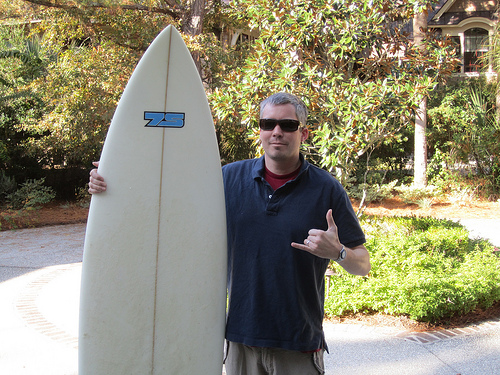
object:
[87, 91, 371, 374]
man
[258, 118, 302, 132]
sunglasses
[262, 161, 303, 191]
undershirt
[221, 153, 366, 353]
shirt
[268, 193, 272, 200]
button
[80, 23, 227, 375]
surfboard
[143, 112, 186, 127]
sticker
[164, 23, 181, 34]
tip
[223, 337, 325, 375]
pants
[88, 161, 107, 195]
hand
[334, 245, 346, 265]
watch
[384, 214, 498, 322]
bush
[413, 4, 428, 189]
tree trunk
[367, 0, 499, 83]
building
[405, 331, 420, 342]
brick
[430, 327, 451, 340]
brick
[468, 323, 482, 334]
brick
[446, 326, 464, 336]
brick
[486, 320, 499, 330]
brick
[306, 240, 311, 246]
wedding band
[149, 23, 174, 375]
line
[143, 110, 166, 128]
seven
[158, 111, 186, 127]
s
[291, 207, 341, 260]
hand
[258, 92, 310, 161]
head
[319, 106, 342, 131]
leaf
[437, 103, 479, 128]
leaf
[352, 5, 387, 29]
leaf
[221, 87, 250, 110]
leaf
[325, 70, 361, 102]
leaf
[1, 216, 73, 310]
concrete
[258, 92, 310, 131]
hair